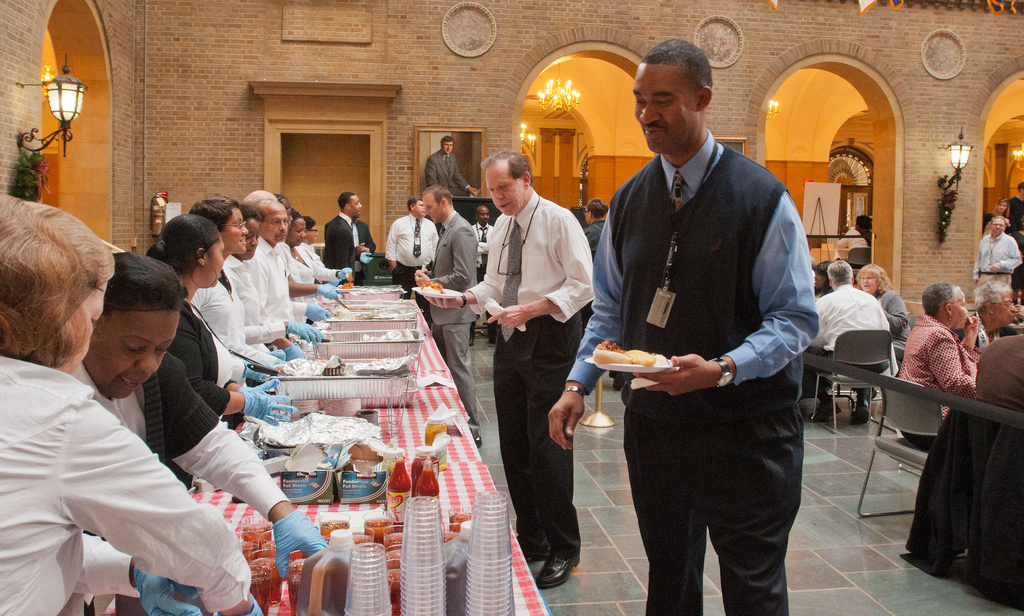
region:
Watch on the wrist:
[708, 353, 734, 388]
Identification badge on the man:
[634, 275, 680, 334]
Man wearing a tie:
[452, 149, 592, 328]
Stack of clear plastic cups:
[462, 473, 526, 614]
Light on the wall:
[927, 126, 975, 240]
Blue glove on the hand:
[229, 364, 303, 431]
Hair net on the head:
[4, 187, 129, 375]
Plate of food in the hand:
[569, 337, 715, 404]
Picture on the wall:
[408, 123, 482, 193]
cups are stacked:
[463, 488, 517, 610]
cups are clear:
[399, 495, 441, 610]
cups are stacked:
[343, 536, 388, 610]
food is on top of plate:
[583, 334, 670, 376]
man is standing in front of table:
[545, 36, 818, 612]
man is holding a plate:
[545, 40, 820, 610]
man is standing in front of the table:
[422, 147, 593, 587]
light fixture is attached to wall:
[17, 49, 85, 157]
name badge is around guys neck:
[645, 138, 721, 328]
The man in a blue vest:
[554, 57, 821, 614]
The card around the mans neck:
[641, 281, 693, 330]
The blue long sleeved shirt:
[561, 155, 802, 390]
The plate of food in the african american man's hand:
[578, 330, 673, 384]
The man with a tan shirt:
[453, 149, 606, 583]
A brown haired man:
[401, 177, 500, 452]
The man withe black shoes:
[445, 139, 613, 560]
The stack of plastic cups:
[460, 482, 531, 610]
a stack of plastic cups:
[452, 482, 523, 612]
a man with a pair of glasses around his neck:
[494, 184, 539, 283]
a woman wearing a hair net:
[0, 213, 117, 368]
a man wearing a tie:
[399, 218, 431, 260]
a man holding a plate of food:
[567, 319, 717, 393]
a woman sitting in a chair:
[886, 289, 976, 537]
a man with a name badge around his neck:
[639, 200, 690, 328]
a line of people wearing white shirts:
[222, 203, 328, 447]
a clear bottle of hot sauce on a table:
[381, 453, 419, 526]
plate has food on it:
[580, 339, 685, 374]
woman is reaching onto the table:
[69, 249, 333, 591]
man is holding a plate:
[403, 149, 599, 592]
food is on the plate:
[405, 263, 470, 301]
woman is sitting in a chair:
[856, 282, 981, 521]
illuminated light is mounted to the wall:
[934, 126, 974, 241]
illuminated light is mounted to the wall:
[13, 54, 84, 203]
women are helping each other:
[0, 190, 333, 614]